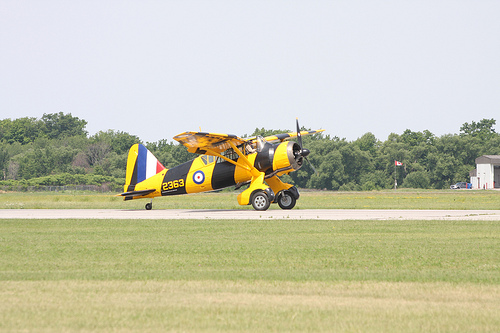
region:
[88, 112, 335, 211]
Plane on the runway.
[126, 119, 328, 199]
The plane is black and yellow.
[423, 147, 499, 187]
A building in the corner of runway.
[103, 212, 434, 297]
The grass is green.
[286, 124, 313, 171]
The propeller on the plane.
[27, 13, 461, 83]
The sky is clear and blue.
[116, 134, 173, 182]
The tail of the plane.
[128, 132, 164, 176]
The tail has red white and blue stripe.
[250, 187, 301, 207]
The wheel of the plane.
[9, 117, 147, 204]
Trees on the side of the runway.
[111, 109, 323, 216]
Plane on the ground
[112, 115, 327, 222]
Plane is on the ground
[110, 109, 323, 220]
Airplane on the ground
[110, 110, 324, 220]
Airplane is on the ground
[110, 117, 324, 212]
Plane on a runway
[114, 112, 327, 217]
Plane is on a runway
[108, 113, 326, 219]
Airplane on a runway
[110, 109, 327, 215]
Airplane is on a runway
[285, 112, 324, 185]
Propellor on front of a plane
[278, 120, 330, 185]
Propellor is on the front of a plane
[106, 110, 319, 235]
yellow and black plane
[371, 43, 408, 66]
white clouds in blue sky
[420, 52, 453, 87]
white clouds in blue sky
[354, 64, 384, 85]
white clouds in blue sky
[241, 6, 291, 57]
white clouds in blue sky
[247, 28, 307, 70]
white clouds in blue sky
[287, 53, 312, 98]
white clouds in blue sky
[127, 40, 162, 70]
white clouds in blue sky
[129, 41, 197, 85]
white clouds in blue sky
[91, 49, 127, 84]
white clouds in blue sky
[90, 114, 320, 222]
airplane on the runway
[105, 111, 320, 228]
yellow plane landed with black stripes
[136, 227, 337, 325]
green and brown dry grass lawn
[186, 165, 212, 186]
red white and blue target on plane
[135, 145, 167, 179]
red white and blue stripes on plane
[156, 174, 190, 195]
numbers painted in yellow on black stripe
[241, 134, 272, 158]
windshield on the plane's cock pit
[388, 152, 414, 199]
Canadian flag on a short post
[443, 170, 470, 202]
car parked near the large trees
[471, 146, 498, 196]
large structure built at the airport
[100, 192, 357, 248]
runway in between the grass lawns